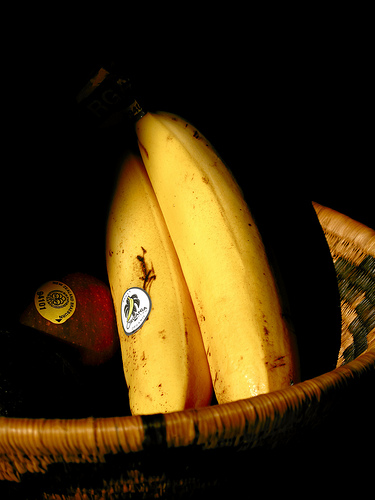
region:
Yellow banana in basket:
[102, 159, 212, 412]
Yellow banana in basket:
[136, 116, 299, 394]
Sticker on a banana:
[111, 281, 158, 335]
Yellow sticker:
[30, 275, 85, 327]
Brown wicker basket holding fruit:
[0, 195, 370, 485]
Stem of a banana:
[112, 77, 157, 123]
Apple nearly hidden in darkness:
[19, 268, 116, 368]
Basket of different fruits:
[0, 104, 373, 453]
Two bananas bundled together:
[72, 96, 307, 421]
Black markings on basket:
[328, 241, 373, 355]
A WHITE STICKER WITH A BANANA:
[113, 289, 149, 338]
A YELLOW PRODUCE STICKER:
[28, 276, 79, 349]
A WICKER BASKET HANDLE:
[324, 244, 374, 358]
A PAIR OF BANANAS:
[104, 248, 294, 415]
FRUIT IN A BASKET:
[19, 258, 226, 429]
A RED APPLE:
[14, 270, 129, 372]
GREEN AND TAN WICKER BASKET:
[319, 207, 373, 410]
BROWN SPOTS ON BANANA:
[118, 338, 190, 409]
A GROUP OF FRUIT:
[12, 76, 239, 362]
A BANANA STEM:
[88, 70, 206, 147]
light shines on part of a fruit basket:
[15, 16, 350, 481]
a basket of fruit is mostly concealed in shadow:
[10, 23, 367, 467]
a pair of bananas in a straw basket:
[85, 109, 318, 446]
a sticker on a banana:
[113, 286, 156, 339]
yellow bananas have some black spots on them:
[89, 108, 296, 433]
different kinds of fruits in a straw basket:
[21, 86, 373, 431]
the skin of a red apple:
[15, 248, 111, 375]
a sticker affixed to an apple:
[36, 280, 83, 333]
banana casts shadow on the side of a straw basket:
[86, 100, 341, 424]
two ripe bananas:
[101, 138, 300, 426]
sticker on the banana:
[101, 275, 158, 351]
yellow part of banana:
[148, 320, 181, 367]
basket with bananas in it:
[49, 399, 111, 463]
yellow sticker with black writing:
[26, 269, 92, 341]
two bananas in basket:
[108, 175, 275, 316]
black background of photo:
[15, 125, 101, 189]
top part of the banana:
[90, 60, 159, 120]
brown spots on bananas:
[123, 240, 176, 282]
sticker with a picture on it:
[98, 285, 159, 348]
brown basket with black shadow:
[112, 401, 222, 479]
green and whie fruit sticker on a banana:
[119, 285, 153, 336]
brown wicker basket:
[2, 199, 374, 496]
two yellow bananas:
[89, 65, 300, 415]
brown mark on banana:
[127, 251, 166, 286]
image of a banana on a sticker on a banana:
[124, 295, 139, 324]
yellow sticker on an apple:
[30, 274, 77, 327]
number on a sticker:
[32, 288, 48, 314]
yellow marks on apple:
[77, 292, 105, 333]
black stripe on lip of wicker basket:
[129, 414, 184, 450]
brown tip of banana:
[87, 67, 148, 115]